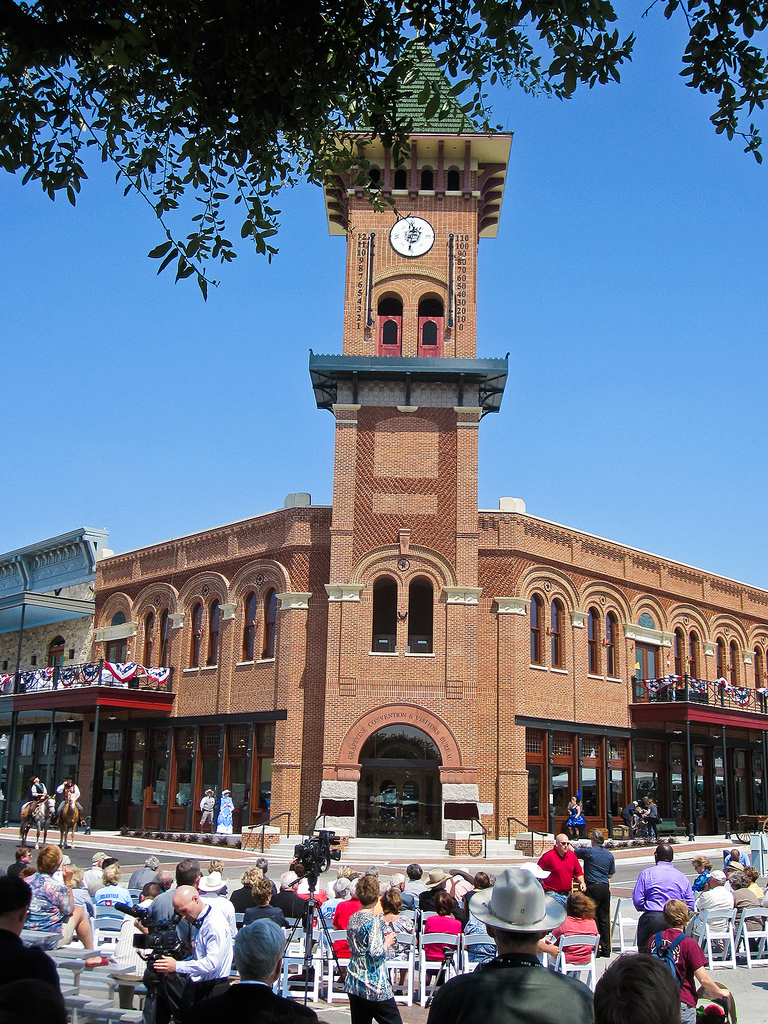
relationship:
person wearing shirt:
[419, 889, 465, 1006] [419, 914, 470, 972]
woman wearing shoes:
[18, 832, 83, 954] [77, 945, 118, 971]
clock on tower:
[387, 216, 434, 257] [304, 67, 515, 511]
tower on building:
[304, 67, 515, 511] [82, 415, 766, 836]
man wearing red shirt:
[398, 868, 603, 1021] [536, 844, 584, 891]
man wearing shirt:
[620, 828, 731, 946] [633, 858, 716, 926]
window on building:
[526, 590, 541, 661] [9, 506, 766, 835]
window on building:
[551, 601, 560, 667] [9, 506, 766, 835]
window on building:
[588, 608, 598, 673] [9, 506, 766, 835]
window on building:
[603, 613, 618, 677] [9, 506, 766, 835]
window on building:
[531, 762, 539, 816] [9, 506, 766, 835]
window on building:
[371, 566, 397, 655] [366, 570, 415, 668]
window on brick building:
[531, 591, 542, 660] [0, 39, 768, 860]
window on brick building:
[588, 602, 603, 679] [0, 39, 768, 860]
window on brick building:
[187, 594, 204, 670] [0, 39, 768, 860]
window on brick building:
[238, 583, 257, 664] [0, 39, 768, 860]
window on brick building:
[637, 609, 657, 630] [0, 39, 768, 860]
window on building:
[583, 606, 622, 679] [68, 28, 765, 845]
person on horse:
[28, 770, 46, 807] [10, 796, 59, 847]